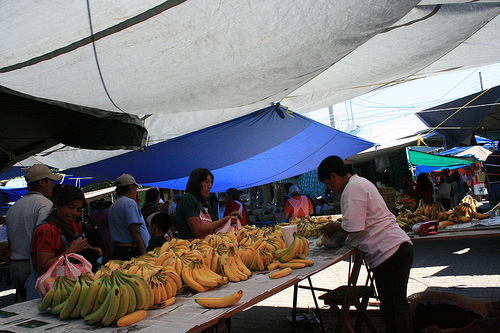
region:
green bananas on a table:
[41, 266, 156, 322]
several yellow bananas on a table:
[151, 217, 311, 316]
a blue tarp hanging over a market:
[26, 119, 380, 207]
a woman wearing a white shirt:
[309, 156, 372, 305]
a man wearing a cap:
[30, 160, 55, 195]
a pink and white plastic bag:
[23, 247, 95, 314]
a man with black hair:
[181, 153, 231, 215]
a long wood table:
[188, 210, 360, 332]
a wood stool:
[324, 275, 376, 332]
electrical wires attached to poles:
[336, 89, 442, 131]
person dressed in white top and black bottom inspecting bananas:
[311, 152, 417, 329]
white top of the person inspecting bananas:
[336, 172, 414, 268]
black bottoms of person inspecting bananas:
[369, 239, 414, 331]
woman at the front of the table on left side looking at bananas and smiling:
[26, 182, 95, 282]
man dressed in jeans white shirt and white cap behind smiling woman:
[7, 164, 64, 297]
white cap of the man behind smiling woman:
[23, 162, 63, 187]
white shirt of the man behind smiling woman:
[7, 192, 53, 259]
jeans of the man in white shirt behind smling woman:
[13, 262, 30, 292]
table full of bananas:
[38, 225, 316, 327]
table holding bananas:
[0, 222, 359, 330]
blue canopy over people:
[62, 79, 453, 201]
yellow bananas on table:
[114, 233, 300, 313]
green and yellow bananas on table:
[37, 238, 174, 330]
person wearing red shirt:
[32, 175, 109, 272]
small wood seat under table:
[222, 235, 423, 330]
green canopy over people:
[382, 129, 497, 206]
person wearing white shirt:
[315, 147, 417, 272]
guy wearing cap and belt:
[102, 167, 155, 257]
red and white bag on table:
[16, 250, 115, 323]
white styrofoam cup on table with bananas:
[261, 211, 323, 276]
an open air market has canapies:
[6, 1, 499, 323]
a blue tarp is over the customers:
[28, 104, 384, 209]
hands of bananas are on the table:
[21, 217, 350, 324]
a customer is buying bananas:
[175, 155, 413, 272]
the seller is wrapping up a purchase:
[306, 153, 418, 274]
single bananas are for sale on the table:
[188, 254, 323, 309]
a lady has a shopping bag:
[26, 180, 103, 305]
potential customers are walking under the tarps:
[0, 146, 499, 234]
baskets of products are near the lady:
[241, 188, 314, 227]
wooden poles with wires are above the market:
[318, 63, 499, 174]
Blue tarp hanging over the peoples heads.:
[223, 110, 296, 181]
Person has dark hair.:
[316, 151, 337, 172]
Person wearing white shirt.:
[339, 193, 376, 245]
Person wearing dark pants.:
[387, 255, 420, 328]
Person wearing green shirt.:
[182, 196, 210, 226]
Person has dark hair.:
[191, 172, 205, 192]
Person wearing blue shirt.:
[107, 199, 158, 239]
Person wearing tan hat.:
[104, 170, 138, 193]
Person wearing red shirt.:
[26, 216, 86, 274]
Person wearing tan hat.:
[19, 153, 68, 196]